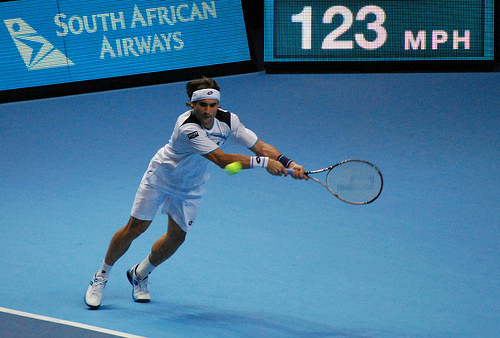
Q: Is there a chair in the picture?
A: No, there are no chairs.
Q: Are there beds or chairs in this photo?
A: No, there are no chairs or beds.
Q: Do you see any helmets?
A: No, there are no helmets.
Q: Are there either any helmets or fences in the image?
A: No, there are no helmets or fences.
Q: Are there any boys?
A: No, there are no boys.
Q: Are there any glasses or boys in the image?
A: No, there are no boys or glasses.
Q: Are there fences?
A: No, there are no fences.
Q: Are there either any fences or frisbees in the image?
A: No, there are no fences or frisbees.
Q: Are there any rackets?
A: Yes, there is a racket.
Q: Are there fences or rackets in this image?
A: Yes, there is a racket.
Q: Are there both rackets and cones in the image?
A: No, there is a racket but no cones.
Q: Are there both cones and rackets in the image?
A: No, there is a racket but no cones.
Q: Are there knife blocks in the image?
A: No, there are no knife blocks.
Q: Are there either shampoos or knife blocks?
A: No, there are no knife blocks or shampoos.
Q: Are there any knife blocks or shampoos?
A: No, there are no knife blocks or shampoos.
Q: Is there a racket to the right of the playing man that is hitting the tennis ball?
A: Yes, there is a racket to the right of the man.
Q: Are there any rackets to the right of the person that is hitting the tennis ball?
A: Yes, there is a racket to the right of the man.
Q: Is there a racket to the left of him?
A: No, the racket is to the right of the man.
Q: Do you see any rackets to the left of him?
A: No, the racket is to the right of the man.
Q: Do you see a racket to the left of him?
A: No, the racket is to the right of the man.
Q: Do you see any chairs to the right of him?
A: No, there is a racket to the right of the man.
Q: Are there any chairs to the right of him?
A: No, there is a racket to the right of the man.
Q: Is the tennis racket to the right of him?
A: Yes, the tennis racket is to the right of the man.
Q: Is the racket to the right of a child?
A: No, the racket is to the right of the man.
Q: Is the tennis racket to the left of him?
A: No, the tennis racket is to the right of a man.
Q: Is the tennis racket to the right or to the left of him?
A: The tennis racket is to the right of the man.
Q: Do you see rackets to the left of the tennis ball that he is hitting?
A: No, the racket is to the right of the tennis ball.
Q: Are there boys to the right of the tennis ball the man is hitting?
A: No, there is a racket to the right of the tennis ball.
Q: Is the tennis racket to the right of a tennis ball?
A: Yes, the tennis racket is to the right of a tennis ball.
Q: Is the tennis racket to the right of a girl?
A: No, the tennis racket is to the right of a tennis ball.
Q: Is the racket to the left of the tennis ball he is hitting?
A: No, the racket is to the right of the tennis ball.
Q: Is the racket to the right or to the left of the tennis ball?
A: The racket is to the right of the tennis ball.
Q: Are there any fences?
A: No, there are no fences.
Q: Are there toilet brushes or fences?
A: No, there are no fences or toilet brushes.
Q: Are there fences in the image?
A: No, there are no fences.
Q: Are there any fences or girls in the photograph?
A: No, there are no fences or girls.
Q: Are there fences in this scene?
A: No, there are no fences.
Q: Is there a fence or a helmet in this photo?
A: No, there are no fences or helmets.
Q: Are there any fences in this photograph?
A: No, there are no fences.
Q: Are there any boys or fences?
A: No, there are no boys or fences.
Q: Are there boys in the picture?
A: No, there are no boys.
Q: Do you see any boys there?
A: No, there are no boys.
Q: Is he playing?
A: Yes, the man is playing.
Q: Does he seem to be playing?
A: Yes, the man is playing.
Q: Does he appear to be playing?
A: Yes, the man is playing.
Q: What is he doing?
A: The man is playing.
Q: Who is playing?
A: The man is playing.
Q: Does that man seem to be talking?
A: No, the man is playing.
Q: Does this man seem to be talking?
A: No, the man is playing.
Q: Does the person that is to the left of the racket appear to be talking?
A: No, the man is playing.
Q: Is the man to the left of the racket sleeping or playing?
A: The man is playing.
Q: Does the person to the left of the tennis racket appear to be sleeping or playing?
A: The man is playing.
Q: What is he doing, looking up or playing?
A: The man is playing.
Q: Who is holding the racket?
A: The man is holding the racket.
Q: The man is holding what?
A: The man is holding the racket.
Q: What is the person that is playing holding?
A: The man is holding the racket.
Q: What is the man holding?
A: The man is holding the racket.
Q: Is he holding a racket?
A: Yes, the man is holding a racket.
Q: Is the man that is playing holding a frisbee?
A: No, the man is holding a racket.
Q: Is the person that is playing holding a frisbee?
A: No, the man is holding a racket.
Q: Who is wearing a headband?
A: The man is wearing a headband.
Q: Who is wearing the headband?
A: The man is wearing a headband.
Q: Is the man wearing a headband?
A: Yes, the man is wearing a headband.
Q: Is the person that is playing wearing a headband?
A: Yes, the man is wearing a headband.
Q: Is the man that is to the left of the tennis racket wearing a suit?
A: No, the man is wearing a headband.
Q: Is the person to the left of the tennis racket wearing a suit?
A: No, the man is wearing a headband.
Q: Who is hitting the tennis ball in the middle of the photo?
A: The man is hitting the tennis ball.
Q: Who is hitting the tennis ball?
A: The man is hitting the tennis ball.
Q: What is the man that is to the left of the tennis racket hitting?
A: The man is hitting the tennis ball.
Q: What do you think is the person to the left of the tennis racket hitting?
A: The man is hitting the tennis ball.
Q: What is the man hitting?
A: The man is hitting the tennis ball.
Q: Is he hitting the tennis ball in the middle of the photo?
A: Yes, the man is hitting the tennis ball.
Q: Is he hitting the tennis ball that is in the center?
A: Yes, the man is hitting the tennis ball.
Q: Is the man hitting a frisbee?
A: No, the man is hitting the tennis ball.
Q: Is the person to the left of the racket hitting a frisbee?
A: No, the man is hitting the tennis ball.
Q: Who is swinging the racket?
A: The man is swinging the racket.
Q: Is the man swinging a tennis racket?
A: Yes, the man is swinging a tennis racket.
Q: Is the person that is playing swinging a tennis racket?
A: Yes, the man is swinging a tennis racket.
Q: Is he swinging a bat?
A: No, the man is swinging a tennis racket.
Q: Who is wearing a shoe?
A: The man is wearing a shoe.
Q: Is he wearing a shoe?
A: Yes, the man is wearing a shoe.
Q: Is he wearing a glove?
A: No, the man is wearing a shoe.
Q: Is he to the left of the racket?
A: Yes, the man is to the left of the racket.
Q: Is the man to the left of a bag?
A: No, the man is to the left of the racket.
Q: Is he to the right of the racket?
A: No, the man is to the left of the racket.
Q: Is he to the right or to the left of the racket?
A: The man is to the left of the racket.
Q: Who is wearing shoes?
A: The man is wearing shoes.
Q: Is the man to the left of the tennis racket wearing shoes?
A: Yes, the man is wearing shoes.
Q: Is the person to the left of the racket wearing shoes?
A: Yes, the man is wearing shoes.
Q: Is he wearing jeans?
A: No, the man is wearing shoes.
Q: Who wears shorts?
A: The man wears shorts.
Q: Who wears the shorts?
A: The man wears shorts.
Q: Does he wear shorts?
A: Yes, the man wears shorts.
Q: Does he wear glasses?
A: No, the man wears shorts.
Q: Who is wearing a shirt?
A: The man is wearing a shirt.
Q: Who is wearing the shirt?
A: The man is wearing a shirt.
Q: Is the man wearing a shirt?
A: Yes, the man is wearing a shirt.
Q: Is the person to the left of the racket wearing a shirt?
A: Yes, the man is wearing a shirt.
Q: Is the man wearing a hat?
A: No, the man is wearing a shirt.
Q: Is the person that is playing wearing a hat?
A: No, the man is wearing a shirt.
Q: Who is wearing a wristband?
A: The man is wearing a wristband.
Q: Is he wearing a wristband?
A: Yes, the man is wearing a wristband.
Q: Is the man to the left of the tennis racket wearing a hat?
A: No, the man is wearing a wristband.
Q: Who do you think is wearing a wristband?
A: The man is wearing a wristband.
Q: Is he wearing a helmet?
A: No, the man is wearing a wristband.